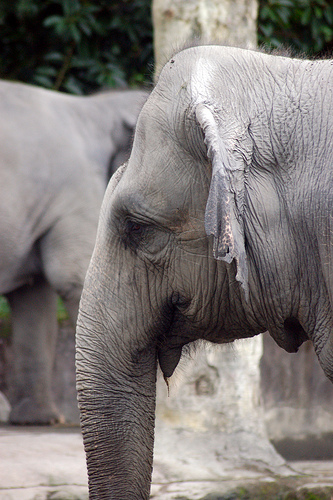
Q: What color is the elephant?
A: Grey.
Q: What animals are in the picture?
A: Elephants.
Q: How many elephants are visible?
A: 2.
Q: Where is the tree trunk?
A: Behind the front elephant.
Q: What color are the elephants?
A: Gray.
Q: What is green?
A: Tree leaves.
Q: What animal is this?
A: Elephant.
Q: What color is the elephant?
A: Gray.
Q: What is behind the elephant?
A: Trunk of tree.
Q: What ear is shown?
A: Left.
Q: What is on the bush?
A: Leaves.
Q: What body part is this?
A: Ear.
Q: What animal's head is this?
A: Elephant.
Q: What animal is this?
A: Elephant.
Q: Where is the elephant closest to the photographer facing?
A: Left.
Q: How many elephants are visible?
A: Two.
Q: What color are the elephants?
A: A chalky grey.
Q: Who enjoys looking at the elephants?
A: People like the photographer.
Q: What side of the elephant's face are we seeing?
A: The left side.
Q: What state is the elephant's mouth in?
A: It's closed.